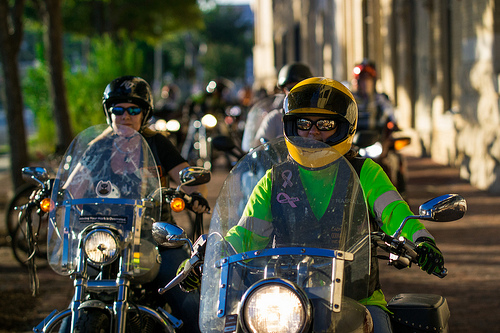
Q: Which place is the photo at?
A: It is at the road.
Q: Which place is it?
A: It is a road.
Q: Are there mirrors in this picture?
A: Yes, there is a mirror.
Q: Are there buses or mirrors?
A: Yes, there is a mirror.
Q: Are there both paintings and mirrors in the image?
A: No, there is a mirror but no paintings.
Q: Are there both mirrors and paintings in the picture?
A: No, there is a mirror but no paintings.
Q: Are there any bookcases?
A: No, there are no bookcases.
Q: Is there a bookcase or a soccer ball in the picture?
A: No, there are no bookcases or soccer balls.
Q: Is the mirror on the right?
A: Yes, the mirror is on the right of the image.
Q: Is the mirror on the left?
A: No, the mirror is on the right of the image.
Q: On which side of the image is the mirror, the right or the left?
A: The mirror is on the right of the image.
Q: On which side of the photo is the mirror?
A: The mirror is on the right of the image.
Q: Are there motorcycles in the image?
A: Yes, there is a motorcycle.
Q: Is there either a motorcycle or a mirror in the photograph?
A: Yes, there is a motorcycle.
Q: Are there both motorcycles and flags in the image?
A: No, there is a motorcycle but no flags.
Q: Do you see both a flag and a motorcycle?
A: No, there is a motorcycle but no flags.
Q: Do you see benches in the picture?
A: No, there are no benches.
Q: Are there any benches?
A: No, there are no benches.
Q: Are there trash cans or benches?
A: No, there are no benches or trash cans.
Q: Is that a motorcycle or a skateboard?
A: That is a motorcycle.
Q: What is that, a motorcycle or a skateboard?
A: That is a motorcycle.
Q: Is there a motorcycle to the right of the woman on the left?
A: Yes, there is a motorcycle to the right of the woman.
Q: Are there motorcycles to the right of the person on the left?
A: Yes, there is a motorcycle to the right of the woman.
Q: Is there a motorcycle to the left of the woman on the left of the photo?
A: No, the motorcycle is to the right of the woman.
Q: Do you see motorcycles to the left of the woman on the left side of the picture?
A: No, the motorcycle is to the right of the woman.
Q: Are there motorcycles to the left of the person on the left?
A: No, the motorcycle is to the right of the woman.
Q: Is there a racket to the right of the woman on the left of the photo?
A: No, there is a motorcycle to the right of the woman.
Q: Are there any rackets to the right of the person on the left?
A: No, there is a motorcycle to the right of the woman.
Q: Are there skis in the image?
A: No, there are no skis.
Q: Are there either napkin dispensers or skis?
A: No, there are no skis or napkin dispensers.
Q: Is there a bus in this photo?
A: No, there are no buses.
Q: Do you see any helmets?
A: Yes, there is a helmet.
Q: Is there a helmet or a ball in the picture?
A: Yes, there is a helmet.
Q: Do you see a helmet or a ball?
A: Yes, there is a helmet.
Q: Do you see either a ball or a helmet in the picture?
A: Yes, there is a helmet.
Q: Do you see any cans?
A: No, there are no cans.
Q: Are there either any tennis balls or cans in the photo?
A: No, there are no cans or tennis balls.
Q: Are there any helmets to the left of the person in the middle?
A: Yes, there is a helmet to the left of the person.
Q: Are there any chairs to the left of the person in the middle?
A: No, there is a helmet to the left of the person.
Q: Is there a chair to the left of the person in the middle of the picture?
A: No, there is a helmet to the left of the person.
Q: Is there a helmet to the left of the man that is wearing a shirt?
A: Yes, there is a helmet to the left of the man.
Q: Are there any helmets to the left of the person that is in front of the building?
A: Yes, there is a helmet to the left of the man.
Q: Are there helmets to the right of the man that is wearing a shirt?
A: No, the helmet is to the left of the man.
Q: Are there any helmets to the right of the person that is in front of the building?
A: No, the helmet is to the left of the man.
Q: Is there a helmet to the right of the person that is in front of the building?
A: No, the helmet is to the left of the man.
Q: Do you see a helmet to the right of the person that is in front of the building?
A: No, the helmet is to the left of the man.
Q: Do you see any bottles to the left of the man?
A: No, there is a helmet to the left of the man.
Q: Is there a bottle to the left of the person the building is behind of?
A: No, there is a helmet to the left of the man.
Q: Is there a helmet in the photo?
A: Yes, there is a helmet.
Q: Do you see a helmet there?
A: Yes, there is a helmet.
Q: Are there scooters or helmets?
A: Yes, there is a helmet.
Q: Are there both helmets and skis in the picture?
A: No, there is a helmet but no skis.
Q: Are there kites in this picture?
A: No, there are no kites.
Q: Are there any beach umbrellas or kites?
A: No, there are no kites or beach umbrellas.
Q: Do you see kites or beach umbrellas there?
A: No, there are no kites or beach umbrellas.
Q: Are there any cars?
A: No, there are no cars.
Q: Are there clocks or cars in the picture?
A: No, there are no cars or clocks.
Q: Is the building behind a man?
A: Yes, the building is behind a man.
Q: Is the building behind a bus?
A: No, the building is behind a man.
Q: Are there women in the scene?
A: Yes, there is a woman.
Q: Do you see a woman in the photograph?
A: Yes, there is a woman.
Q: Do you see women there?
A: Yes, there is a woman.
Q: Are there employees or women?
A: Yes, there is a woman.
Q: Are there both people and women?
A: Yes, there are both a woman and people.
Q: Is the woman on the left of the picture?
A: Yes, the woman is on the left of the image.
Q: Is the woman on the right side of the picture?
A: No, the woman is on the left of the image.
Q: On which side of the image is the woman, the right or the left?
A: The woman is on the left of the image.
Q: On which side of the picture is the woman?
A: The woman is on the left of the image.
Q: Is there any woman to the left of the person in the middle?
A: Yes, there is a woman to the left of the person.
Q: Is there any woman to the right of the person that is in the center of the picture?
A: No, the woman is to the left of the person.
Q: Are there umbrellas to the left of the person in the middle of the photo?
A: No, there is a woman to the left of the person.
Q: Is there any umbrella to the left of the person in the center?
A: No, there is a woman to the left of the person.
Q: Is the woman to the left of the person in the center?
A: Yes, the woman is to the left of the person.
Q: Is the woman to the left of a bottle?
A: No, the woman is to the left of the person.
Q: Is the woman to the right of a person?
A: No, the woman is to the left of a person.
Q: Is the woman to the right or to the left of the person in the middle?
A: The woman is to the left of the person.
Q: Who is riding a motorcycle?
A: The woman is riding a motorcycle.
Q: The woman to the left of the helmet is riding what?
A: The woman is riding a motorcycle.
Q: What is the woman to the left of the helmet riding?
A: The woman is riding a motorcycle.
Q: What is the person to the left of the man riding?
A: The woman is riding a motorcycle.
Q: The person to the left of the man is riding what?
A: The woman is riding a motorcycle.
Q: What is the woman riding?
A: The woman is riding a motorcycle.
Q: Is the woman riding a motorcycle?
A: Yes, the woman is riding a motorcycle.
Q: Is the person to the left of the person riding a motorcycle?
A: Yes, the woman is riding a motorcycle.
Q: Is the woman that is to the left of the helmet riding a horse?
A: No, the woman is riding a motorcycle.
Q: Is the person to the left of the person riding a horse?
A: No, the woman is riding a motorcycle.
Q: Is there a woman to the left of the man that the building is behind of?
A: Yes, there is a woman to the left of the man.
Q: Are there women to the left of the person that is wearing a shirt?
A: Yes, there is a woman to the left of the man.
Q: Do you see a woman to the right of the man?
A: No, the woman is to the left of the man.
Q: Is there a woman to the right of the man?
A: No, the woman is to the left of the man.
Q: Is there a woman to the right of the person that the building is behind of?
A: No, the woman is to the left of the man.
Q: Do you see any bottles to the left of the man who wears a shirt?
A: No, there is a woman to the left of the man.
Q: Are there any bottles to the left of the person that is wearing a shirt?
A: No, there is a woman to the left of the man.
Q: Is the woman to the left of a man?
A: Yes, the woman is to the left of a man.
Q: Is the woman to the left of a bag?
A: No, the woman is to the left of a man.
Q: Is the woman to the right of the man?
A: No, the woman is to the left of the man.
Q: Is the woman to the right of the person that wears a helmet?
A: No, the woman is to the left of the man.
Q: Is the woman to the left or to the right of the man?
A: The woman is to the left of the man.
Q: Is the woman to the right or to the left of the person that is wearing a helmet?
A: The woman is to the left of the man.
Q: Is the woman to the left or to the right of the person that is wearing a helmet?
A: The woman is to the left of the man.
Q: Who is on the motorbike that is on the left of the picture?
A: The woman is on the motorcycle.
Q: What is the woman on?
A: The woman is on the motorcycle.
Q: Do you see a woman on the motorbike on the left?
A: Yes, there is a woman on the motorcycle.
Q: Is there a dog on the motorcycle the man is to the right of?
A: No, there is a woman on the motorcycle.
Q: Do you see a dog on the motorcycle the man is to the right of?
A: No, there is a woman on the motorcycle.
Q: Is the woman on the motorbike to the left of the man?
A: Yes, the woman is on the motorbike.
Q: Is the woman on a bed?
A: No, the woman is on the motorbike.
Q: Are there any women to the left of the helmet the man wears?
A: Yes, there is a woman to the left of the helmet.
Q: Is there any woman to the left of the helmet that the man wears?
A: Yes, there is a woman to the left of the helmet.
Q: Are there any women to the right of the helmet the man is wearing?
A: No, the woman is to the left of the helmet.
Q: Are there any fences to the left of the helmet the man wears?
A: No, there is a woman to the left of the helmet.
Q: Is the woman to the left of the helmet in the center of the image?
A: Yes, the woman is to the left of the helmet.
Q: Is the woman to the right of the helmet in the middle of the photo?
A: No, the woman is to the left of the helmet.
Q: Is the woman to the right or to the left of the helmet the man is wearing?
A: The woman is to the left of the helmet.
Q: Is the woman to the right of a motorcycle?
A: No, the woman is to the left of a motorcycle.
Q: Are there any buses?
A: No, there are no buses.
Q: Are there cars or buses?
A: No, there are no buses or cars.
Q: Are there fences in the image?
A: No, there are no fences.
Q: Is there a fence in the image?
A: No, there are no fences.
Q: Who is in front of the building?
A: The man is in front of the building.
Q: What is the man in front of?
A: The man is in front of the building.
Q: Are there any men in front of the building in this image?
A: Yes, there is a man in front of the building.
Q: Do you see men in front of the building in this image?
A: Yes, there is a man in front of the building.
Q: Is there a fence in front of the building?
A: No, there is a man in front of the building.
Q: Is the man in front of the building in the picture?
A: Yes, the man is in front of the building.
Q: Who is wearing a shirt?
A: The man is wearing a shirt.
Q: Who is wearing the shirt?
A: The man is wearing a shirt.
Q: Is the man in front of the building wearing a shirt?
A: Yes, the man is wearing a shirt.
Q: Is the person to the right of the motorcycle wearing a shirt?
A: Yes, the man is wearing a shirt.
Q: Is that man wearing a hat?
A: No, the man is wearing a shirt.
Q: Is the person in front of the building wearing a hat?
A: No, the man is wearing a shirt.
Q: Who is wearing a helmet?
A: The man is wearing a helmet.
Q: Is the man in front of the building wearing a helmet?
A: Yes, the man is wearing a helmet.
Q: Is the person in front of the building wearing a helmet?
A: Yes, the man is wearing a helmet.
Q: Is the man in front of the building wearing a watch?
A: No, the man is wearing a helmet.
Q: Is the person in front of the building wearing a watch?
A: No, the man is wearing a helmet.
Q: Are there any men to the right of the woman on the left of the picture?
A: Yes, there is a man to the right of the woman.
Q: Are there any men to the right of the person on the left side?
A: Yes, there is a man to the right of the woman.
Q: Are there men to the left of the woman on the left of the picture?
A: No, the man is to the right of the woman.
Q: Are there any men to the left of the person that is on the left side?
A: No, the man is to the right of the woman.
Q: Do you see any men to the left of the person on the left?
A: No, the man is to the right of the woman.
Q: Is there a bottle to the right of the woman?
A: No, there is a man to the right of the woman.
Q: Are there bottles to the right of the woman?
A: No, there is a man to the right of the woman.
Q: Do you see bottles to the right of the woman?
A: No, there is a man to the right of the woman.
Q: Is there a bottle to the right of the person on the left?
A: No, there is a man to the right of the woman.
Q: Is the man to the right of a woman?
A: Yes, the man is to the right of a woman.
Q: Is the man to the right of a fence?
A: No, the man is to the right of a woman.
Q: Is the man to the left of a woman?
A: No, the man is to the right of a woman.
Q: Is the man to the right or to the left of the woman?
A: The man is to the right of the woman.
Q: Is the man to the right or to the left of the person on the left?
A: The man is to the right of the woman.